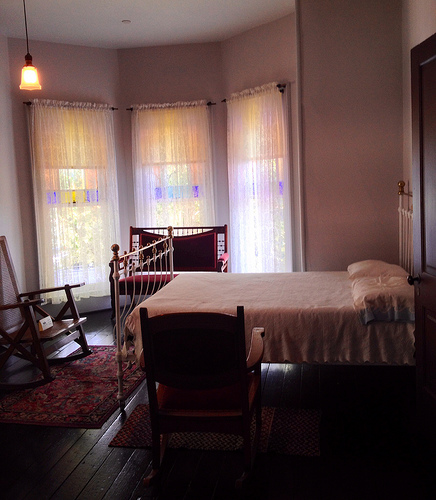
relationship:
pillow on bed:
[352, 273, 413, 322] [143, 239, 432, 382]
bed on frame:
[108, 225, 416, 414] [108, 226, 174, 410]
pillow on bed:
[348, 258, 406, 279] [154, 264, 413, 320]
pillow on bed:
[352, 273, 413, 322] [154, 264, 413, 320]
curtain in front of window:
[128, 95, 217, 237] [135, 104, 207, 237]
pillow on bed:
[352, 273, 413, 322] [133, 210, 410, 368]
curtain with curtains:
[31, 98, 121, 309] [21, 92, 128, 306]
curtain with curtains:
[128, 95, 217, 237] [125, 95, 220, 235]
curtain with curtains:
[220, 84, 293, 272] [219, 80, 296, 268]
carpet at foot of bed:
[0, 342, 148, 430] [124, 269, 412, 363]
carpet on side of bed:
[108, 397, 333, 452] [103, 234, 431, 419]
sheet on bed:
[135, 257, 413, 369] [99, 233, 427, 383]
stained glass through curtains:
[138, 113, 214, 204] [128, 98, 219, 264]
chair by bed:
[0, 234, 93, 381] [108, 225, 416, 414]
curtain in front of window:
[220, 84, 293, 272] [231, 101, 289, 273]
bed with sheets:
[124, 258, 415, 367] [124, 270, 414, 369]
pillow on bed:
[352, 273, 413, 322] [108, 225, 416, 414]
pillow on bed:
[348, 258, 406, 279] [108, 225, 416, 414]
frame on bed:
[110, 178, 412, 412] [103, 199, 434, 423]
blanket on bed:
[123, 257, 414, 365] [104, 226, 434, 436]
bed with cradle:
[108, 225, 416, 414] [66, 223, 245, 290]